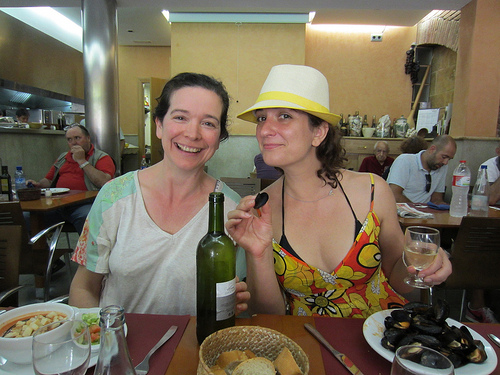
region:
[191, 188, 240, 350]
green glass bottle of wine on table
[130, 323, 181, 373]
silver metal fork on table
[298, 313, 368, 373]
silver metal knife on table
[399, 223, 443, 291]
clear round glass of white wine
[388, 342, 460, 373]
clear glass near white plate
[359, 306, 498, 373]
circular white plate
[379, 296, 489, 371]
pile of black shellfish on white plate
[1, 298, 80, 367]
circular white bowl of soup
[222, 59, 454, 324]
woman wearing white and yellow hat sitting at table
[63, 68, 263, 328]
woman in white shirt sitting at table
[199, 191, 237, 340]
a green bottle of wine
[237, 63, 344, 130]
a yellow and white hat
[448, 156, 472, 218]
a large bottle of water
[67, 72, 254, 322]
a woman wearing a white green and pink shirt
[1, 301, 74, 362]
a bowl of soup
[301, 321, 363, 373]
a knife on the table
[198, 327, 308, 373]
a basket of bread slices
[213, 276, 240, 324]
the label on a wine bottle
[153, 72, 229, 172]
a woman smiling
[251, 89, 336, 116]
the yellow stripe on a hat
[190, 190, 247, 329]
the bottle on the table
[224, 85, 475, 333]
the woman holding the glass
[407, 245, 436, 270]
the wine in the glass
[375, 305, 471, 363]
the clams on the plate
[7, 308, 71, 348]
the soup on the plate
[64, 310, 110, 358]
the salad beside the soup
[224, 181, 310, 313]
the woman holding the clam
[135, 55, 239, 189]
the woman is smiling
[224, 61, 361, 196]
the woman wearing the hat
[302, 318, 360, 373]
the knife on the table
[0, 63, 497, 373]
two women seated on the same side of a table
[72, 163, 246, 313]
woman is wearing a loose fitting v-necked top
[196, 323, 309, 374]
woven basket holding pieces of bread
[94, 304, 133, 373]
top of an open, clear glass bottle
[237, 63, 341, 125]
woman wearing a white hat with a yellow band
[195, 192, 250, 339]
woman touching a green bottle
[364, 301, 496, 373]
plate full of oysters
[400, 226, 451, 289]
woman holding a short-stemmed glass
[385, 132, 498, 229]
man at table in background is looking down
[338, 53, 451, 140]
decorative items on distant shelf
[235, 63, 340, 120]
woman wearing a yelow hat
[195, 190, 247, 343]
woman touching a bottle of wine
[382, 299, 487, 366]
mussels on a white plate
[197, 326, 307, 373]
a wicker basket containing loafs of bread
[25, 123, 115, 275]
man sitting at a table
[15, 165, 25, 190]
a bottle of water on a table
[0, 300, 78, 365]
a bowl of pasta soup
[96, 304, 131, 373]
tip of a glass bottle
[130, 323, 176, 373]
a fork on a red place mat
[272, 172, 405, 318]
woman wearing a colorful summer dress